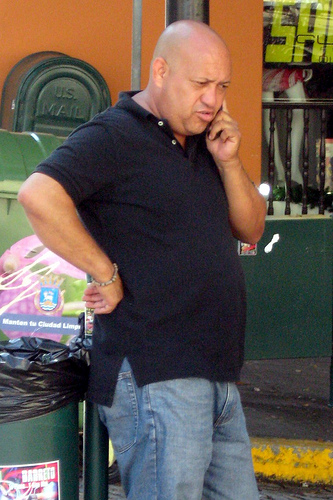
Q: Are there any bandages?
A: No, there are no bandages.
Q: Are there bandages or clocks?
A: No, there are no bandages or clocks.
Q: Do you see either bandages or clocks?
A: No, there are no bandages or clocks.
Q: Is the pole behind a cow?
A: No, the pole is behind the man.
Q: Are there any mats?
A: No, there are no mats.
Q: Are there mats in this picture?
A: No, there are no mats.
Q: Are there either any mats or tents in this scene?
A: No, there are no mats or tents.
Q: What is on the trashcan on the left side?
A: The sticker is on the trashcan.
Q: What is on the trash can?
A: The sticker is on the trashcan.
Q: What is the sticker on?
A: The sticker is on the garbage bin.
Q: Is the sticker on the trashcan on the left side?
A: Yes, the sticker is on the garbage can.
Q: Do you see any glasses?
A: No, there are no glasses.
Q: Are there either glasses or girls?
A: No, there are no glasses or girls.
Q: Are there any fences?
A: Yes, there is a fence.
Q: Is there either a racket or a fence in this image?
A: Yes, there is a fence.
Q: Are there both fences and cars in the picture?
A: No, there is a fence but no cars.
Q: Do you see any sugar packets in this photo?
A: No, there are no sugar packets.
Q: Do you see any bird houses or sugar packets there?
A: No, there are no sugar packets or bird houses.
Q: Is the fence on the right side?
A: Yes, the fence is on the right of the image.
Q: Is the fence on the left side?
A: No, the fence is on the right of the image.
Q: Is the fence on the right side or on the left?
A: The fence is on the right of the image.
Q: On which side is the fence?
A: The fence is on the right of the image.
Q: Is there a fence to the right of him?
A: Yes, there is a fence to the right of the man.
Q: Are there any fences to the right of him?
A: Yes, there is a fence to the right of the man.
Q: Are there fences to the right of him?
A: Yes, there is a fence to the right of the man.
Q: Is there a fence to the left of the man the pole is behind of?
A: No, the fence is to the right of the man.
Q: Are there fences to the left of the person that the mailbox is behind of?
A: No, the fence is to the right of the man.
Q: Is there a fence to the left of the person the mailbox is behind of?
A: No, the fence is to the right of the man.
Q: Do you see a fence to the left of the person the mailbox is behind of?
A: No, the fence is to the right of the man.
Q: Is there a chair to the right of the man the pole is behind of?
A: No, there is a fence to the right of the man.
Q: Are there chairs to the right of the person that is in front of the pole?
A: No, there is a fence to the right of the man.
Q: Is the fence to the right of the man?
A: Yes, the fence is to the right of the man.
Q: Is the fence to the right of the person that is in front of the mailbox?
A: Yes, the fence is to the right of the man.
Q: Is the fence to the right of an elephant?
A: No, the fence is to the right of the man.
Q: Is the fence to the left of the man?
A: No, the fence is to the right of the man.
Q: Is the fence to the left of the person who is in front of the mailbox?
A: No, the fence is to the right of the man.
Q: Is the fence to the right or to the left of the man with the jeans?
A: The fence is to the right of the man.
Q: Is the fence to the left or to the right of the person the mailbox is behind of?
A: The fence is to the right of the man.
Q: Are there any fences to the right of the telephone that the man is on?
A: Yes, there is a fence to the right of the telephone.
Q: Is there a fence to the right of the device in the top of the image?
A: Yes, there is a fence to the right of the telephone.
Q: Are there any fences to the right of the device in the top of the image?
A: Yes, there is a fence to the right of the telephone.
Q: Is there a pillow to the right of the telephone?
A: No, there is a fence to the right of the telephone.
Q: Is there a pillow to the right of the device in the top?
A: No, there is a fence to the right of the telephone.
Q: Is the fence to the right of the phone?
A: Yes, the fence is to the right of the phone.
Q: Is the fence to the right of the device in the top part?
A: Yes, the fence is to the right of the phone.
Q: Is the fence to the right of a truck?
A: No, the fence is to the right of the phone.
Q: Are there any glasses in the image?
A: No, there are no glasses.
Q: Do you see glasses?
A: No, there are no glasses.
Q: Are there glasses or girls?
A: No, there are no glasses or girls.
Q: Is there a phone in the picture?
A: Yes, there is a phone.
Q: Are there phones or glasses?
A: Yes, there is a phone.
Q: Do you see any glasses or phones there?
A: Yes, there is a phone.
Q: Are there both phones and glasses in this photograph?
A: No, there is a phone but no glasses.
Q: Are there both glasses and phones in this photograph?
A: No, there is a phone but no glasses.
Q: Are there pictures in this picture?
A: No, there are no pictures.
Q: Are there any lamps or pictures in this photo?
A: No, there are no pictures or lamps.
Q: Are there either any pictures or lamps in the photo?
A: No, there are no pictures or lamps.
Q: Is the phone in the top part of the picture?
A: Yes, the phone is in the top of the image.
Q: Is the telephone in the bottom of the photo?
A: No, the telephone is in the top of the image.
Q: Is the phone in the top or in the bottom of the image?
A: The phone is in the top of the image.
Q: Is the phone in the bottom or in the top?
A: The phone is in the top of the image.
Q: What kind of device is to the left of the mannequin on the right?
A: The device is a phone.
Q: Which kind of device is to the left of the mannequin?
A: The device is a phone.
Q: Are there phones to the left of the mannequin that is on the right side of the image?
A: Yes, there is a phone to the left of the mannequin.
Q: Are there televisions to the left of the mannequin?
A: No, there is a phone to the left of the mannequin.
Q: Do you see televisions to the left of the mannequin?
A: No, there is a phone to the left of the mannequin.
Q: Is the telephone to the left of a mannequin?
A: Yes, the telephone is to the left of a mannequin.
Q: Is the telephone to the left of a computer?
A: No, the telephone is to the left of a mannequin.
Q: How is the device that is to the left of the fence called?
A: The device is a phone.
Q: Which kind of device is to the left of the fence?
A: The device is a phone.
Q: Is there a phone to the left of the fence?
A: Yes, there is a phone to the left of the fence.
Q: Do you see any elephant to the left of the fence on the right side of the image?
A: No, there is a phone to the left of the fence.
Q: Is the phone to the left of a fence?
A: Yes, the phone is to the left of a fence.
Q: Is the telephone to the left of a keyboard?
A: No, the telephone is to the left of a fence.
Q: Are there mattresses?
A: No, there are no mattresses.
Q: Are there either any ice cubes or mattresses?
A: No, there are no mattresses or ice cubes.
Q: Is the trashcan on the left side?
A: Yes, the trashcan is on the left of the image.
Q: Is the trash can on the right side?
A: No, the trash can is on the left of the image.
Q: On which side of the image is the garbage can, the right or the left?
A: The garbage can is on the left of the image.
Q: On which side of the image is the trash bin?
A: The trash bin is on the left of the image.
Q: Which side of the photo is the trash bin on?
A: The trash bin is on the left of the image.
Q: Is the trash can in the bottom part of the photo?
A: Yes, the trash can is in the bottom of the image.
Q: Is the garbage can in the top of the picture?
A: No, the garbage can is in the bottom of the image.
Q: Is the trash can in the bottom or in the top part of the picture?
A: The trash can is in the bottom of the image.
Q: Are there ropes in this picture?
A: No, there are no ropes.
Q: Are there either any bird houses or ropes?
A: No, there are no ropes or bird houses.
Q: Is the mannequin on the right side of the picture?
A: Yes, the mannequin is on the right of the image.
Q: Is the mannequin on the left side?
A: No, the mannequin is on the right of the image.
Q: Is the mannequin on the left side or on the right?
A: The mannequin is on the right of the image.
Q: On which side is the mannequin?
A: The mannequin is on the right of the image.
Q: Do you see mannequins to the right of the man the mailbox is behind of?
A: Yes, there is a mannequin to the right of the man.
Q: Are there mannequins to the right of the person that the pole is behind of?
A: Yes, there is a mannequin to the right of the man.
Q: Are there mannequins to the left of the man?
A: No, the mannequin is to the right of the man.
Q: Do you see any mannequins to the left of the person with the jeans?
A: No, the mannequin is to the right of the man.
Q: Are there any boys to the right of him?
A: No, there is a mannequin to the right of the man.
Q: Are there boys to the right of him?
A: No, there is a mannequin to the right of the man.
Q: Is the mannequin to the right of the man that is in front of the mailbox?
A: Yes, the mannequin is to the right of the man.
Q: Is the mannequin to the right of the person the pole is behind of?
A: Yes, the mannequin is to the right of the man.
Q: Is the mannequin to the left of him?
A: No, the mannequin is to the right of the man.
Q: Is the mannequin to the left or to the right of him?
A: The mannequin is to the right of the man.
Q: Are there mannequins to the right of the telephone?
A: Yes, there is a mannequin to the right of the telephone.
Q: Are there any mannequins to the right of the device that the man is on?
A: Yes, there is a mannequin to the right of the telephone.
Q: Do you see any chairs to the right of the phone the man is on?
A: No, there is a mannequin to the right of the telephone.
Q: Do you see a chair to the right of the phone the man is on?
A: No, there is a mannequin to the right of the telephone.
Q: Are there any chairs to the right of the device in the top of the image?
A: No, there is a mannequin to the right of the telephone.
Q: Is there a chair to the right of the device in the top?
A: No, there is a mannequin to the right of the telephone.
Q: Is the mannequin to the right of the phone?
A: Yes, the mannequin is to the right of the phone.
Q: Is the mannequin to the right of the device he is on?
A: Yes, the mannequin is to the right of the phone.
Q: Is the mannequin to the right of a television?
A: No, the mannequin is to the right of the phone.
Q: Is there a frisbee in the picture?
A: No, there are no frisbees.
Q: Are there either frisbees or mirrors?
A: No, there are no frisbees or mirrors.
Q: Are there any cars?
A: No, there are no cars.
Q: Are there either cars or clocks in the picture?
A: No, there are no cars or clocks.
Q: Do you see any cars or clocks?
A: No, there are no cars or clocks.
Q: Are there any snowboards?
A: No, there are no snowboards.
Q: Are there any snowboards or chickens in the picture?
A: No, there are no snowboards or chickens.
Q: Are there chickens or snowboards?
A: No, there are no snowboards or chickens.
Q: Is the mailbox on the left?
A: Yes, the mailbox is on the left of the image.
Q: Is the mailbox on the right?
A: No, the mailbox is on the left of the image.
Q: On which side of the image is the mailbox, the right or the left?
A: The mailbox is on the left of the image.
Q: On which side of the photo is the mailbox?
A: The mailbox is on the left of the image.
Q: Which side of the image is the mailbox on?
A: The mailbox is on the left of the image.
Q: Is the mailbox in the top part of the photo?
A: Yes, the mailbox is in the top of the image.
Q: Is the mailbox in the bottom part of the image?
A: No, the mailbox is in the top of the image.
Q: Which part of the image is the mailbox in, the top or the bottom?
A: The mailbox is in the top of the image.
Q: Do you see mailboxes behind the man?
A: Yes, there is a mailbox behind the man.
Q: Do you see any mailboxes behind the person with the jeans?
A: Yes, there is a mailbox behind the man.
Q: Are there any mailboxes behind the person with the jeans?
A: Yes, there is a mailbox behind the man.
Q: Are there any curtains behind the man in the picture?
A: No, there is a mailbox behind the man.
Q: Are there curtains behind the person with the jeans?
A: No, there is a mailbox behind the man.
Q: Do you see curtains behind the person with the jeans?
A: No, there is a mailbox behind the man.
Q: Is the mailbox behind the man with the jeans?
A: Yes, the mailbox is behind the man.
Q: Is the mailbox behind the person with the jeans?
A: Yes, the mailbox is behind the man.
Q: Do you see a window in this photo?
A: Yes, there is a window.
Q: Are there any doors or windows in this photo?
A: Yes, there is a window.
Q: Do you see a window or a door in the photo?
A: Yes, there is a window.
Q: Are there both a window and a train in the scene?
A: No, there is a window but no trains.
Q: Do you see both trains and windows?
A: No, there is a window but no trains.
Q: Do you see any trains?
A: No, there are no trains.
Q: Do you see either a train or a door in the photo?
A: No, there are no trains or doors.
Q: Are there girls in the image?
A: No, there are no girls.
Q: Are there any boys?
A: No, there are no boys.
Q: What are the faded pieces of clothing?
A: The clothing items are jeans.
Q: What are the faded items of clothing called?
A: The clothing items are jeans.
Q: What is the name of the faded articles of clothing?
A: The clothing items are jeans.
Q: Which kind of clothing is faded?
A: The clothing is jeans.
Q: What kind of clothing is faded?
A: The clothing is jeans.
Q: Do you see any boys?
A: No, there are no boys.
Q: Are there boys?
A: No, there are no boys.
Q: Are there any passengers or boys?
A: No, there are no boys or passengers.